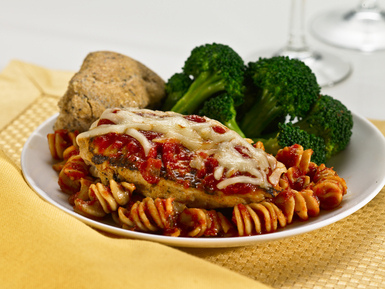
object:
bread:
[49, 52, 166, 133]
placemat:
[0, 58, 273, 289]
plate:
[20, 108, 384, 249]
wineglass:
[266, 0, 352, 88]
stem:
[287, 5, 305, 51]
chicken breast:
[75, 110, 287, 207]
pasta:
[114, 192, 176, 236]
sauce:
[164, 142, 187, 161]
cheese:
[139, 116, 157, 131]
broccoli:
[156, 43, 245, 121]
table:
[0, 0, 384, 120]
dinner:
[25, 44, 385, 248]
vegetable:
[237, 56, 321, 137]